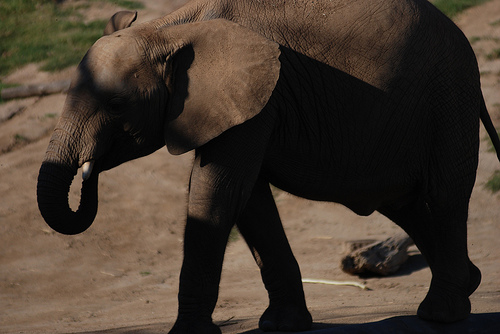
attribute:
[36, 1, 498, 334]
elephant — close, wrinkled, hairy, walking, alone, lit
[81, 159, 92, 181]
tusk — small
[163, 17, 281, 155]
ear — large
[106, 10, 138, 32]
ear — large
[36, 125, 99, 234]
trunk — curled, long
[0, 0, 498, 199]
grass — green, growing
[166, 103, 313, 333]
legs — hairy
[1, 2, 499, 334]
ground — dirty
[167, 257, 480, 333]
feet — large